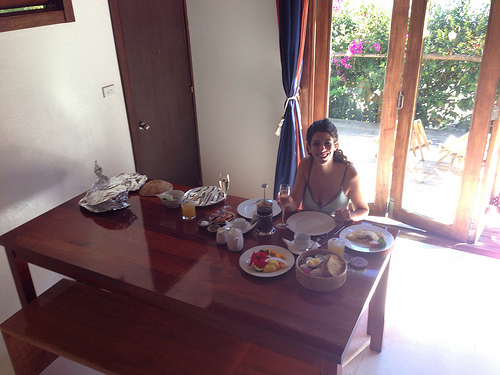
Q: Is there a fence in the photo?
A: No, there are no fences.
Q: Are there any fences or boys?
A: No, there are no fences or boys.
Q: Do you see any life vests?
A: No, there are no life vests.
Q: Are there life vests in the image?
A: No, there are no life vests.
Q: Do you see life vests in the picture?
A: No, there are no life vests.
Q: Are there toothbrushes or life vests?
A: No, there are no life vests or toothbrushes.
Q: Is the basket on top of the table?
A: Yes, the basket is on top of the table.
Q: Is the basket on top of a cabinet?
A: No, the basket is on top of the table.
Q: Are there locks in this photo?
A: No, there are no locks.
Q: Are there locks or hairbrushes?
A: No, there are no locks or hairbrushes.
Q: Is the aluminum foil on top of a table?
A: Yes, the foil is on top of a table.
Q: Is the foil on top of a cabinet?
A: No, the foil is on top of a table.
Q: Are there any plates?
A: Yes, there is a plate.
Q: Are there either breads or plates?
A: Yes, there is a plate.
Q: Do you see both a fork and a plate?
A: No, there is a plate but no forks.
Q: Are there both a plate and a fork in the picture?
A: No, there is a plate but no forks.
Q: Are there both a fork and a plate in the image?
A: No, there is a plate but no forks.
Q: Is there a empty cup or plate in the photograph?
A: Yes, there is an empty plate.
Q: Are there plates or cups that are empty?
A: Yes, the plate is empty.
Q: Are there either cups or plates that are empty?
A: Yes, the plate is empty.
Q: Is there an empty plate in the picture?
A: Yes, there is an empty plate.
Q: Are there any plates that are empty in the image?
A: Yes, there is an empty plate.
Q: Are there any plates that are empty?
A: Yes, there is a plate that is empty.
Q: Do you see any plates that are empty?
A: Yes, there is a plate that is empty.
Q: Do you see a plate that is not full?
A: Yes, there is a empty plate.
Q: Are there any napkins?
A: No, there are no napkins.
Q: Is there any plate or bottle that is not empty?
A: No, there is a plate but it is empty.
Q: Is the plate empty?
A: Yes, the plate is empty.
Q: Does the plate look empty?
A: Yes, the plate is empty.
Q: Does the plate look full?
A: No, the plate is empty.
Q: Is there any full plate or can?
A: No, there is a plate but it is empty.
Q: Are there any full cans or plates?
A: No, there is a plate but it is empty.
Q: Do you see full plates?
A: No, there is a plate but it is empty.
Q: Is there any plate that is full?
A: No, there is a plate but it is empty.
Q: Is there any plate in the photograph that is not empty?
A: No, there is a plate but it is empty.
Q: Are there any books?
A: No, there are no books.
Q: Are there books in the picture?
A: No, there are no books.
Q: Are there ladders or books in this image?
A: No, there are no books or ladders.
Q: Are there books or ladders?
A: No, there are no books or ladders.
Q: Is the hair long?
A: Yes, the hair is long.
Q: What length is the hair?
A: The hair is long.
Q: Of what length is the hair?
A: The hair is long.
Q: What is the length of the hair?
A: The hair is long.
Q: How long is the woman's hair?
A: The hair is long.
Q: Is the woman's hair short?
A: No, the hair is long.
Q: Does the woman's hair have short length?
A: No, the hair is long.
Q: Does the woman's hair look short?
A: No, the hair is long.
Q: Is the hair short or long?
A: The hair is long.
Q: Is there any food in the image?
A: Yes, there is food.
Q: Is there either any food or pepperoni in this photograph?
A: Yes, there is food.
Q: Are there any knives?
A: No, there are no knives.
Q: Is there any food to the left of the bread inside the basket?
A: Yes, there is food to the left of the bread.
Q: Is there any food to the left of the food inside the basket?
A: Yes, there is food to the left of the bread.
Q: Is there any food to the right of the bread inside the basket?
A: No, the food is to the left of the bread.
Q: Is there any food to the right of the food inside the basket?
A: No, the food is to the left of the bread.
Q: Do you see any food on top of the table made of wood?
A: Yes, there is food on top of the table.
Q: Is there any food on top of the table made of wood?
A: Yes, there is food on top of the table.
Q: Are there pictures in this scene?
A: No, there are no pictures.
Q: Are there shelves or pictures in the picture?
A: No, there are no pictures or shelves.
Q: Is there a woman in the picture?
A: Yes, there is a woman.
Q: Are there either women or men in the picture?
A: Yes, there is a woman.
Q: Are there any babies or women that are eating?
A: Yes, the woman is eating.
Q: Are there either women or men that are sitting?
A: Yes, the woman is sitting.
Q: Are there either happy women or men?
A: Yes, there is a happy woman.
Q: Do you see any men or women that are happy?
A: Yes, the woman is happy.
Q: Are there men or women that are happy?
A: Yes, the woman is happy.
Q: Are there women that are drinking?
A: Yes, there is a woman that is drinking.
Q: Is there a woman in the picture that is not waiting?
A: Yes, there is a woman that is drinking.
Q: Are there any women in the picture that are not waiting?
A: Yes, there is a woman that is drinking.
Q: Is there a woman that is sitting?
A: Yes, there is a woman that is sitting.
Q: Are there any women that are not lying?
A: Yes, there is a woman that is sitting.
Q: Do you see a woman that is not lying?
A: Yes, there is a woman that is sitting .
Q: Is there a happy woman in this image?
A: Yes, there is a happy woman.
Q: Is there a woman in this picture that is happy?
A: Yes, there is a woman that is happy.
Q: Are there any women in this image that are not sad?
A: Yes, there is a happy woman.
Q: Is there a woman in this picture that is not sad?
A: Yes, there is a happy woman.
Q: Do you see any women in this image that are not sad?
A: Yes, there is a happy woman.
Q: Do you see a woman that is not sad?
A: Yes, there is a happy woman.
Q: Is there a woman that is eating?
A: Yes, there is a woman that is eating.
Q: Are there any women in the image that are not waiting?
A: Yes, there is a woman that is eating.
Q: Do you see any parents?
A: No, there are no parents.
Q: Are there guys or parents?
A: No, there are no parents or guys.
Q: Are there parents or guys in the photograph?
A: No, there are no parents or guys.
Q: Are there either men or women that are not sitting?
A: No, there is a woman but she is sitting.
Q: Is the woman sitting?
A: Yes, the woman is sitting.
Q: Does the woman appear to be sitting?
A: Yes, the woman is sitting.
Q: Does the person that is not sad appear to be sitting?
A: Yes, the woman is sitting.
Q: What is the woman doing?
A: The woman is sitting.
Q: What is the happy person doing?
A: The woman is sitting.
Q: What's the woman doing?
A: The woman is sitting.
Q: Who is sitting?
A: The woman is sitting.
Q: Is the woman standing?
A: No, the woman is sitting.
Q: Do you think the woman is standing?
A: No, the woman is sitting.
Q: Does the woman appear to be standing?
A: No, the woman is sitting.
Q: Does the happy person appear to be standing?
A: No, the woman is sitting.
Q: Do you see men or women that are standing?
A: No, there is a woman but she is sitting.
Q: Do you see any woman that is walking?
A: No, there is a woman but she is sitting.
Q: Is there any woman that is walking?
A: No, there is a woman but she is sitting.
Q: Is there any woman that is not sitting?
A: No, there is a woman but she is sitting.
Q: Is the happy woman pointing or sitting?
A: The woman is sitting.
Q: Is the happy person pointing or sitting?
A: The woman is sitting.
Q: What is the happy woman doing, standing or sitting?
A: The woman is sitting.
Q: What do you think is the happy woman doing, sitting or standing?
A: The woman is sitting.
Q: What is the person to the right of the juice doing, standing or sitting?
A: The woman is sitting.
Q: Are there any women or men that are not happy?
A: No, there is a woman but she is happy.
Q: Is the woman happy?
A: Yes, the woman is happy.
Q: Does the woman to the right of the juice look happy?
A: Yes, the woman is happy.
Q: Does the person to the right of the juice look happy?
A: Yes, the woman is happy.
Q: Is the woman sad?
A: No, the woman is happy.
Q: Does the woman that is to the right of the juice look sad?
A: No, the woman is happy.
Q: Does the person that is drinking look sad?
A: No, the woman is happy.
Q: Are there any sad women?
A: No, there is a woman but she is happy.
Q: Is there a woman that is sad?
A: No, there is a woman but she is happy.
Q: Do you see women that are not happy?
A: No, there is a woman but she is happy.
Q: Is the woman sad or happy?
A: The woman is happy.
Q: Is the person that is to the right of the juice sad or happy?
A: The woman is happy.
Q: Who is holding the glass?
A: The woman is holding the glass.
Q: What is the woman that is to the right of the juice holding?
A: The woman is holding the glass.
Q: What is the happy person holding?
A: The woman is holding the glass.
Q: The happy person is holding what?
A: The woman is holding the glass.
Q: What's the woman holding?
A: The woman is holding the glass.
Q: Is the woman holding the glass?
A: Yes, the woman is holding the glass.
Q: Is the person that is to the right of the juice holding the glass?
A: Yes, the woman is holding the glass.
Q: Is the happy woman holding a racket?
A: No, the woman is holding the glass.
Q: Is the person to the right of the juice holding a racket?
A: No, the woman is holding the glass.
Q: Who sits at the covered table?
A: The woman sits at the table.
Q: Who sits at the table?
A: The woman sits at the table.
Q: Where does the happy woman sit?
A: The woman sits at the table.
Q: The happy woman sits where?
A: The woman sits at the table.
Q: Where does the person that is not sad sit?
A: The woman sits at the table.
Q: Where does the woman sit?
A: The woman sits at the table.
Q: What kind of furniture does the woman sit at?
A: The woman sits at the table.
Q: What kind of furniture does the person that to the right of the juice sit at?
A: The woman sits at the table.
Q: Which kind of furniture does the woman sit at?
A: The woman sits at the table.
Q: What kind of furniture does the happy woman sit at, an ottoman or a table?
A: The woman sits at a table.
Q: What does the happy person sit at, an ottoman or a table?
A: The woman sits at a table.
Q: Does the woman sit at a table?
A: Yes, the woman sits at a table.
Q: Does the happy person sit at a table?
A: Yes, the woman sits at a table.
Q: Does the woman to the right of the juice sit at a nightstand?
A: No, the woman sits at a table.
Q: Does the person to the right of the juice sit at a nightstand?
A: No, the woman sits at a table.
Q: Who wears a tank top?
A: The woman wears a tank top.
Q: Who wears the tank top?
A: The woman wears a tank top.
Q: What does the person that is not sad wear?
A: The woman wears a tank top.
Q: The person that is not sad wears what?
A: The woman wears a tank top.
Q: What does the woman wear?
A: The woman wears a tank top.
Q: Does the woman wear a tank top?
A: Yes, the woman wears a tank top.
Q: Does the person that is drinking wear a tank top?
A: Yes, the woman wears a tank top.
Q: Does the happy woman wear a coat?
A: No, the woman wears a tank top.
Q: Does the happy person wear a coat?
A: No, the woman wears a tank top.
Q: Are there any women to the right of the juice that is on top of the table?
A: Yes, there is a woman to the right of the juice.